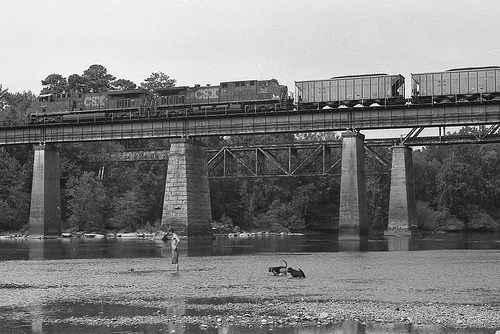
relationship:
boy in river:
[167, 225, 184, 271] [21, 236, 486, 308]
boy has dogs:
[167, 225, 184, 271] [264, 259, 311, 285]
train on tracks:
[28, 66, 496, 102] [18, 103, 486, 120]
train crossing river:
[28, 66, 496, 102] [21, 236, 486, 308]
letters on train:
[81, 94, 107, 108] [28, 66, 496, 102]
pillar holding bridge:
[159, 140, 221, 244] [9, 104, 495, 248]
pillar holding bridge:
[23, 141, 69, 240] [9, 104, 495, 248]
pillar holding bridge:
[334, 133, 430, 249] [9, 104, 495, 248]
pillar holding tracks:
[159, 140, 221, 244] [18, 103, 486, 120]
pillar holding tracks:
[23, 141, 69, 240] [18, 103, 486, 120]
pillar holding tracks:
[334, 133, 430, 249] [18, 103, 486, 120]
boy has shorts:
[167, 225, 184, 271] [171, 246, 181, 261]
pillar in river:
[159, 140, 221, 244] [21, 236, 486, 308]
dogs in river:
[264, 259, 311, 285] [21, 236, 486, 308]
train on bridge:
[28, 66, 496, 102] [9, 104, 495, 248]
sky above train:
[127, 9, 465, 50] [28, 66, 496, 102]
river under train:
[21, 236, 486, 308] [28, 66, 496, 102]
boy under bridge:
[167, 225, 184, 271] [9, 104, 495, 248]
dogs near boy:
[264, 259, 311, 285] [167, 225, 184, 271]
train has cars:
[28, 66, 496, 102] [288, 66, 495, 104]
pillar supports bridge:
[159, 140, 221, 244] [9, 104, 495, 248]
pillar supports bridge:
[23, 141, 69, 240] [9, 104, 495, 248]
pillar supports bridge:
[334, 133, 430, 249] [9, 104, 495, 248]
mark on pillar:
[157, 210, 217, 240] [159, 140, 221, 244]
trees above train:
[44, 62, 175, 89] [28, 66, 496, 102]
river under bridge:
[21, 236, 486, 308] [9, 104, 495, 248]